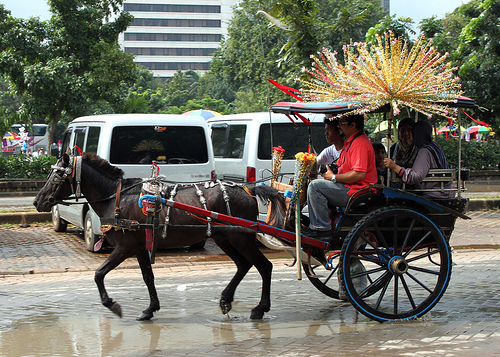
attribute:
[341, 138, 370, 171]
shirt — red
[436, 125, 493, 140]
umbrella — multicolored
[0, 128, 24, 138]
umbrella — multicolored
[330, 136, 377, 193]
shirt — red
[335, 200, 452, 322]
round wheel — big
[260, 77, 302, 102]
streamer — red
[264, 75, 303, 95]
streamer — red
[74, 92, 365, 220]
cars — parked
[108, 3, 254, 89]
building — tall, white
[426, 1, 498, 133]
tree — green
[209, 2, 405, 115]
tree — green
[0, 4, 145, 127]
tree — green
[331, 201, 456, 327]
wheel — black, blue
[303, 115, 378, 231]
man — sitting